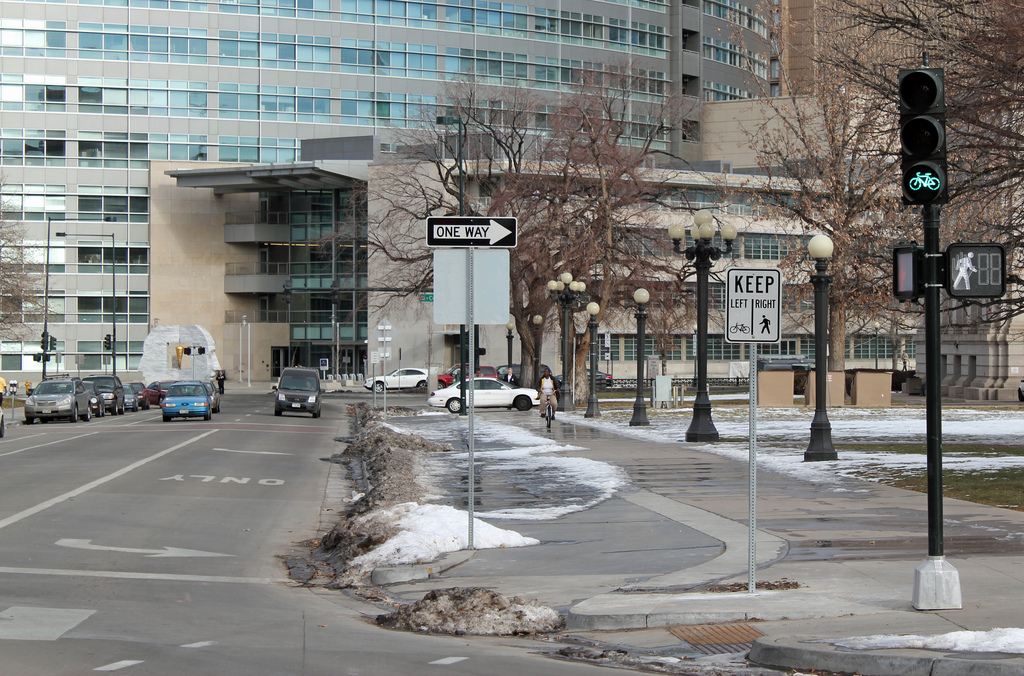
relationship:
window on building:
[73, 128, 108, 164] [259, 109, 342, 434]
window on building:
[296, 73, 317, 119] [229, 103, 392, 287]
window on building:
[342, 26, 359, 77] [123, 103, 171, 205]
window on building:
[125, 237, 154, 275] [99, 148, 179, 369]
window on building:
[104, 191, 130, 224] [35, 103, 142, 473]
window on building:
[372, 39, 392, 77] [78, 103, 126, 372]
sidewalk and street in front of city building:
[351, 407, 725, 611] [39, 105, 450, 503]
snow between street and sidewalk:
[348, 529, 552, 676] [261, 473, 341, 676]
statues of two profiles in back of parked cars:
[125, 313, 242, 405] [104, 351, 329, 431]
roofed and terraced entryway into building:
[235, 205, 302, 279] [173, 110, 405, 454]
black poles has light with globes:
[525, 200, 855, 463] [495, 233, 761, 352]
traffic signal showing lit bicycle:
[887, 60, 957, 219] [812, 116, 972, 337]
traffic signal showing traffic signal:
[888, 234, 1022, 312] [893, 242, 1006, 297]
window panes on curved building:
[2, 3, 683, 140] [160, 103, 273, 227]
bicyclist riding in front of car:
[454, 358, 571, 428] [538, 271, 578, 598]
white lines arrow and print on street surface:
[0, 414, 355, 592] [168, 419, 272, 676]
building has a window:
[95, 198, 162, 350] [119, 74, 152, 116]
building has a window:
[0, 0, 779, 386] [481, 41, 508, 86]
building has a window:
[0, 0, 779, 386] [531, 48, 552, 88]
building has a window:
[0, 0, 779, 386] [500, 45, 526, 90]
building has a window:
[0, 0, 779, 386] [106, 240, 129, 278]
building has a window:
[0, 0, 779, 386] [76, 22, 112, 58]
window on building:
[256, 32, 282, 65] [5, 5, 814, 379]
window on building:
[402, 33, 442, 84] [5, 5, 814, 379]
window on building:
[103, 36, 130, 62] [5, 5, 814, 379]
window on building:
[183, 24, 387, 237] [5, 5, 814, 379]